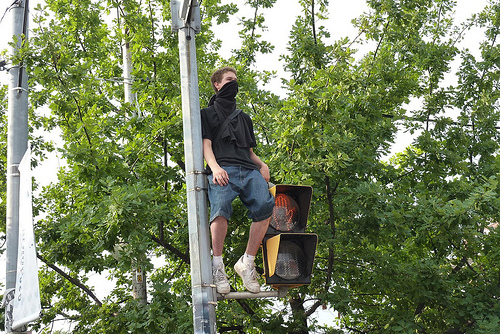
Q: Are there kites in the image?
A: No, there are no kites.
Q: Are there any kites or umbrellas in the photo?
A: No, there are no kites or umbrellas.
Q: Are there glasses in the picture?
A: No, there are no glasses.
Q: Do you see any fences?
A: No, there are no fences.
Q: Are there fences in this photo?
A: No, there are no fences.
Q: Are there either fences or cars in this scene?
A: No, there are no fences or cars.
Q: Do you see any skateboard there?
A: No, there are no skateboards.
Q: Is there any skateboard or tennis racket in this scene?
A: No, there are no skateboards or rackets.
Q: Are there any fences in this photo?
A: No, there are no fences.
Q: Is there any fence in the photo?
A: No, there are no fences.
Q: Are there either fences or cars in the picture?
A: No, there are no fences or cars.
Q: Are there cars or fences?
A: No, there are no fences or cars.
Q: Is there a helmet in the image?
A: No, there are no helmets.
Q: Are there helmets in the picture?
A: No, there are no helmets.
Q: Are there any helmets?
A: No, there are no helmets.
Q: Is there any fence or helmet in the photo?
A: No, there are no helmets or fences.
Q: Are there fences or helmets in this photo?
A: No, there are no helmets or fences.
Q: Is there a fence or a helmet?
A: No, there are no helmets or fences.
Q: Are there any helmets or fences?
A: No, there are no helmets or fences.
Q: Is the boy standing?
A: Yes, the boy is standing.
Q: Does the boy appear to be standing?
A: Yes, the boy is standing.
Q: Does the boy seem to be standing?
A: Yes, the boy is standing.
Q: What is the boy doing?
A: The boy is standing.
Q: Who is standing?
A: The boy is standing.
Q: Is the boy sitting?
A: No, the boy is standing.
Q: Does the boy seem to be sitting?
A: No, the boy is standing.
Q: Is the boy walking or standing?
A: The boy is standing.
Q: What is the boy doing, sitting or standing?
A: The boy is standing.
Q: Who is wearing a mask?
A: The boy is wearing a mask.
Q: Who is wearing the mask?
A: The boy is wearing a mask.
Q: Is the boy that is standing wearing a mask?
A: Yes, the boy is wearing a mask.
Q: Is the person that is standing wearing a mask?
A: Yes, the boy is wearing a mask.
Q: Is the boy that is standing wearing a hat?
A: No, the boy is wearing a mask.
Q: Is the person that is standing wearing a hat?
A: No, the boy is wearing a mask.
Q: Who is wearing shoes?
A: The boy is wearing shoes.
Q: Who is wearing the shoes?
A: The boy is wearing shoes.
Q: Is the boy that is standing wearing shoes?
A: Yes, the boy is wearing shoes.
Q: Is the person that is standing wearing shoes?
A: Yes, the boy is wearing shoes.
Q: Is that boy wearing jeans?
A: No, the boy is wearing shoes.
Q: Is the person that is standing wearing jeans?
A: No, the boy is wearing shoes.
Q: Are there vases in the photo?
A: No, there are no vases.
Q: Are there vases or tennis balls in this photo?
A: No, there are no vases or tennis balls.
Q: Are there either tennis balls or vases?
A: No, there are no vases or tennis balls.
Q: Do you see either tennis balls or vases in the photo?
A: No, there are no vases or tennis balls.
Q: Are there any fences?
A: No, there are no fences.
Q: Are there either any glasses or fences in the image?
A: No, there are no fences or glasses.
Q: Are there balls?
A: No, there are no balls.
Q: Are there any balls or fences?
A: No, there are no balls or fences.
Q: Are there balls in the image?
A: No, there are no balls.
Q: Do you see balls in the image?
A: No, there are no balls.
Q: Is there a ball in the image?
A: No, there are no balls.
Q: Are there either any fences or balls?
A: No, there are no balls or fences.